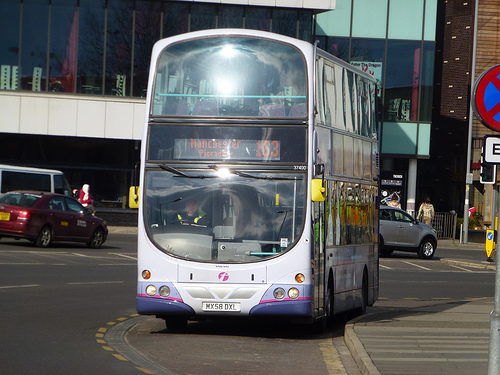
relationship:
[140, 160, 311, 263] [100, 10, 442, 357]
windshield on bus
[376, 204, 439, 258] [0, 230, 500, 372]
car on street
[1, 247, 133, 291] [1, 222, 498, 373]
lines painted on road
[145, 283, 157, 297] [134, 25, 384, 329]
light on bus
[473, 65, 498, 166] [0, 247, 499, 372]
sign on road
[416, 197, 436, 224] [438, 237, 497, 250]
person on sidewalk